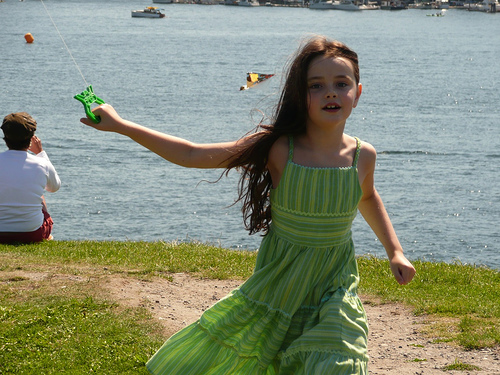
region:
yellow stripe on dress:
[345, 169, 357, 210]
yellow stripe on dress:
[331, 168, 345, 215]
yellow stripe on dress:
[321, 170, 331, 215]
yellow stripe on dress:
[306, 170, 316, 210]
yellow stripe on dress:
[291, 166, 303, 211]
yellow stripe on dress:
[280, 165, 290, 210]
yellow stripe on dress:
[270, 201, 350, 226]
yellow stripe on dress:
[270, 220, 350, 240]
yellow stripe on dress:
[151, 330, 201, 370]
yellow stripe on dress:
[168, 340, 208, 369]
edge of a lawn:
[432, 304, 449, 327]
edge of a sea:
[116, 202, 118, 207]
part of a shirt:
[18, 178, 32, 186]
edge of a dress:
[236, 312, 251, 330]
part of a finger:
[399, 275, 405, 308]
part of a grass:
[161, 271, 172, 296]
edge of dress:
[220, 284, 254, 319]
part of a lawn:
[414, 287, 434, 311]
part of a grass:
[428, 312, 446, 338]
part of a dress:
[340, 283, 354, 304]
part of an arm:
[391, 239, 421, 269]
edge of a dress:
[224, 362, 231, 369]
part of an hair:
[250, 204, 258, 217]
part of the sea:
[423, 177, 457, 217]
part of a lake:
[194, 222, 202, 230]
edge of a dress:
[207, 315, 212, 321]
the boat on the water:
[130, 8, 165, 19]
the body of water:
[0, 0, 498, 273]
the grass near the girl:
[1, 238, 498, 373]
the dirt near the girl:
[0, 253, 498, 373]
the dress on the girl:
[145, 134, 369, 373]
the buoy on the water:
[24, 32, 32, 43]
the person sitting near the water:
[0, 110, 60, 242]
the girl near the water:
[80, 33, 416, 373]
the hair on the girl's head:
[196, 33, 359, 237]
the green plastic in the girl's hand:
[73, 84, 105, 124]